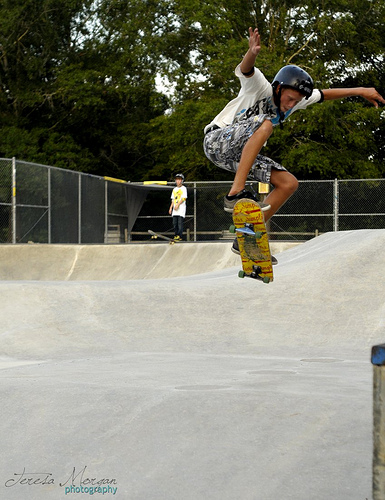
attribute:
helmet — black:
[272, 65, 314, 101]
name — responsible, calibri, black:
[3, 462, 121, 498]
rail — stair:
[368, 343, 382, 498]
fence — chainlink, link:
[1, 153, 382, 244]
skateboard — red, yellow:
[230, 197, 277, 284]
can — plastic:
[102, 224, 121, 245]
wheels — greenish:
[228, 222, 263, 243]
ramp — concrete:
[228, 228, 382, 296]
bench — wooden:
[123, 228, 321, 243]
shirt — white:
[203, 63, 323, 135]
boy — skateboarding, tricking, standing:
[201, 26, 383, 265]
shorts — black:
[203, 116, 288, 189]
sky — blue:
[69, 0, 118, 54]